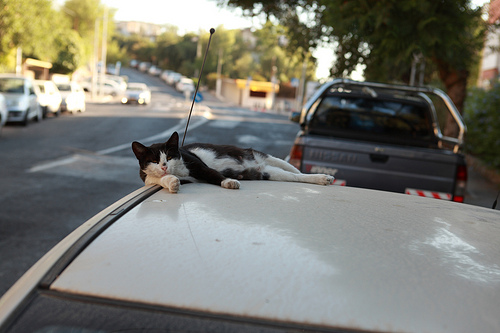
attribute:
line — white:
[24, 99, 213, 176]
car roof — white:
[1, 180, 496, 331]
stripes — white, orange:
[404, 185, 454, 202]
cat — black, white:
[131, 130, 341, 192]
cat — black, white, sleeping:
[125, 128, 337, 195]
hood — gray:
[1, 168, 496, 329]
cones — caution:
[248, 94, 275, 111]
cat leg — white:
[262, 164, 336, 185]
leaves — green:
[319, 20, 484, 62]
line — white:
[32, 144, 126, 166]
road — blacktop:
[0, 60, 354, 332]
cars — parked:
[34, 53, 165, 118]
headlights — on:
[116, 90, 148, 105]